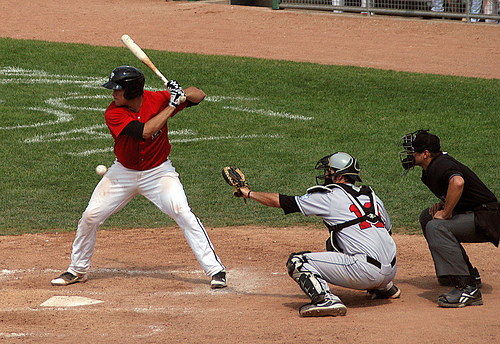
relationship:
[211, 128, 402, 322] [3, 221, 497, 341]
catcher on dirt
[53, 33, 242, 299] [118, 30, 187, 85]
batter holding bat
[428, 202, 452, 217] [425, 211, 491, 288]
hands are on legs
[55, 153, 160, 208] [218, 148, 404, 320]
baseball flying about to get caught by catcher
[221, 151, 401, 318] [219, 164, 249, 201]
catcher wearing baseball glove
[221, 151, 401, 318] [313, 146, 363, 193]
catcher wearing face guard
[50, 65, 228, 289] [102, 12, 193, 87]
batter holding bat.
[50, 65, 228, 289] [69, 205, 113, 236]
batter has knee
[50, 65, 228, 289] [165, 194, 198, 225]
batter has knee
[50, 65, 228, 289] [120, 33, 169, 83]
batter swinging baseball bat